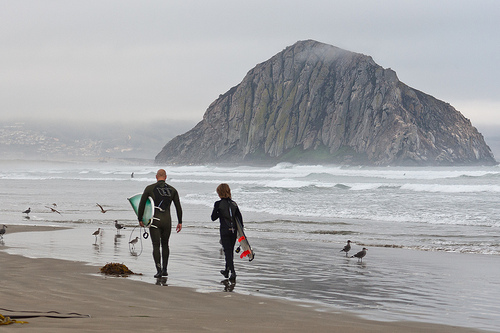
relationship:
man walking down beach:
[138, 169, 184, 277] [0, 158, 484, 316]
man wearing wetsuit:
[138, 169, 184, 277] [211, 199, 243, 268]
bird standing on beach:
[349, 233, 384, 260] [48, 159, 497, 328]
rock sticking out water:
[153, 38, 498, 168] [1, 157, 498, 331]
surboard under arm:
[127, 188, 158, 228] [131, 181, 152, 230]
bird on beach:
[91, 224, 103, 242] [1, 252, 483, 331]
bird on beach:
[95, 202, 110, 213] [1, 252, 483, 331]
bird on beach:
[21, 205, 31, 217] [1, 252, 483, 331]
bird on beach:
[0, 220, 9, 238] [1, 252, 483, 331]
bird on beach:
[126, 235, 138, 250] [1, 252, 483, 331]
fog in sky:
[0, 0, 499, 119] [2, 0, 499, 126]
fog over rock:
[0, 0, 479, 35] [284, 36, 459, 148]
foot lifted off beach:
[219, 266, 231, 278] [0, 183, 499, 332]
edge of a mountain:
[312, 39, 397, 81] [160, 39, 494, 168]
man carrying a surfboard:
[129, 167, 196, 301] [125, 193, 158, 227]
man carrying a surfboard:
[209, 175, 264, 297] [230, 211, 257, 270]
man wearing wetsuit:
[138, 169, 184, 277] [137, 181, 182, 280]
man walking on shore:
[138, 169, 184, 277] [5, 118, 479, 330]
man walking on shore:
[211, 183, 244, 279] [3, 181, 497, 330]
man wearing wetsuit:
[211, 183, 244, 279] [206, 199, 269, 301]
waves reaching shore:
[254, 177, 344, 194] [257, 281, 329, 323]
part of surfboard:
[240, 239, 255, 261] [231, 208, 254, 261]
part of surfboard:
[233, 217, 254, 263] [231, 208, 254, 261]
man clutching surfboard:
[211, 183, 244, 279] [227, 200, 263, 267]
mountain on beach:
[201, 39, 443, 176] [2, 181, 497, 329]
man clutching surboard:
[138, 169, 184, 277] [126, 193, 154, 227]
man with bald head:
[138, 169, 184, 277] [152, 167, 167, 182]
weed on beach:
[81, 250, 146, 280] [14, 194, 446, 331]